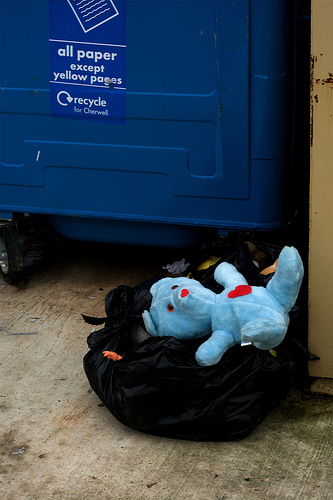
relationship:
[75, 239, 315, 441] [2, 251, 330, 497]
bag on ground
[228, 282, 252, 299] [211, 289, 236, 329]
heart on chest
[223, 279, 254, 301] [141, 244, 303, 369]
red heart on surface of bear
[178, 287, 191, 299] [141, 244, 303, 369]
red heart on surface of bear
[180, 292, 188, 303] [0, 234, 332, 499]
heart nose on ground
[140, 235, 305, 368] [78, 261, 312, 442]
teddy bear lying on bag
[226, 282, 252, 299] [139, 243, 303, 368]
heart on bear